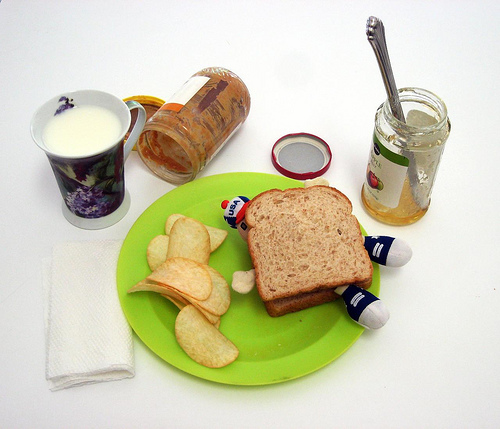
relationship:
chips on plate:
[136, 212, 256, 377] [116, 171, 383, 389]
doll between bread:
[217, 190, 414, 336] [235, 184, 381, 316]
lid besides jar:
[268, 126, 344, 183] [356, 84, 456, 234]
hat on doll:
[214, 193, 253, 228] [217, 190, 414, 336]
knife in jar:
[363, 13, 429, 210] [356, 84, 456, 234]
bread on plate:
[235, 184, 381, 316] [116, 171, 383, 389]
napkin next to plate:
[43, 243, 142, 394] [116, 171, 383, 389]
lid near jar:
[268, 126, 344, 183] [356, 84, 456, 234]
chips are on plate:
[136, 212, 256, 377] [116, 171, 383, 389]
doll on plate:
[221, 176, 413, 329] [116, 171, 383, 389]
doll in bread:
[217, 190, 414, 336] [235, 184, 381, 316]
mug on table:
[25, 87, 152, 237] [4, 2, 494, 428]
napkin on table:
[43, 243, 142, 394] [4, 2, 494, 428]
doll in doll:
[217, 190, 414, 336] [221, 176, 413, 329]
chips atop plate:
[136, 212, 256, 377] [116, 171, 383, 389]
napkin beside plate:
[43, 243, 142, 394] [116, 171, 383, 389]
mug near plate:
[25, 87, 152, 237] [116, 171, 383, 389]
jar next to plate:
[356, 84, 456, 234] [116, 171, 383, 389]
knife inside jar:
[363, 13, 429, 210] [356, 84, 456, 234]